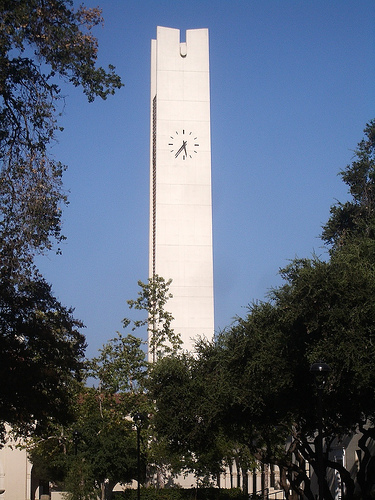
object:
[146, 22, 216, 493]
monument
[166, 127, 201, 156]
clock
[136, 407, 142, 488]
light post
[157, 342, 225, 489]
trees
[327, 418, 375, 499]
building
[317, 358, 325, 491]
light post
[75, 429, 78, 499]
light post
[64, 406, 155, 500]
trees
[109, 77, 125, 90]
leaves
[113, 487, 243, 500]
hedges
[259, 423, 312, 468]
branch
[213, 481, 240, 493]
edge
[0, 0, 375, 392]
sky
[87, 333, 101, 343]
clouds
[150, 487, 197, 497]
grass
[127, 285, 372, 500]
trees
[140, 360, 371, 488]
row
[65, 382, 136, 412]
roof